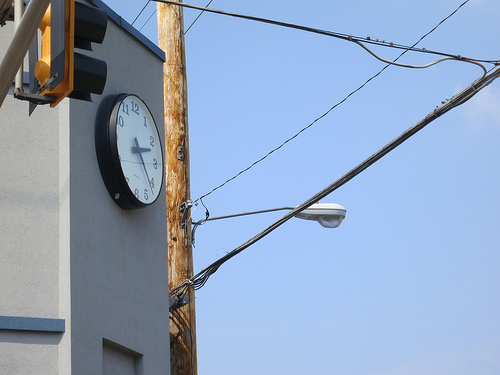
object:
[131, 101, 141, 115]
numbers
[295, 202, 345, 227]
light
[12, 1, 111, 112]
stop light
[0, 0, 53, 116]
pole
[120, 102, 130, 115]
number 11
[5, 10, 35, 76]
pole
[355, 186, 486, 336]
eye wear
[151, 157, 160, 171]
3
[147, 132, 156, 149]
number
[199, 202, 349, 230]
lamp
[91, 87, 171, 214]
string beans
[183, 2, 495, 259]
power lines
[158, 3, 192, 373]
pole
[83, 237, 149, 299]
wall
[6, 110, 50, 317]
gray side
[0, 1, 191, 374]
building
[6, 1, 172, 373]
sunlight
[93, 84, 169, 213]
clock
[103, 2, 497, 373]
sky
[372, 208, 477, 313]
clouds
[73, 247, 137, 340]
decoration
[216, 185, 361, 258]
street light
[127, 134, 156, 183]
handle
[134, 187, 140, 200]
number